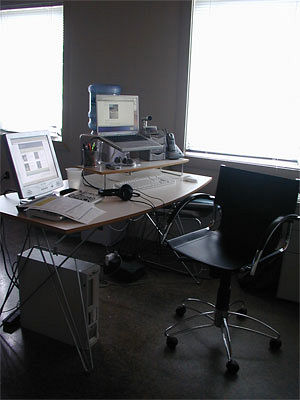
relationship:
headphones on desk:
[95, 181, 141, 203] [0, 154, 220, 380]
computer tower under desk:
[15, 245, 100, 355] [0, 154, 220, 380]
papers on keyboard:
[21, 193, 108, 228] [21, 187, 108, 226]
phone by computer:
[161, 128, 186, 161] [1, 148, 216, 398]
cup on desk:
[64, 165, 85, 191] [0, 154, 220, 380]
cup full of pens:
[76, 148, 101, 172] [81, 138, 96, 166]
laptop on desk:
[91, 89, 167, 153] [0, 154, 220, 380]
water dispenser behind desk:
[82, 79, 126, 172] [1, 146, 219, 398]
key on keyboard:
[132, 181, 140, 185] [104, 172, 177, 196]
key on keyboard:
[132, 177, 140, 185] [102, 173, 182, 198]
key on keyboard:
[143, 176, 150, 183] [104, 172, 177, 196]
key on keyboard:
[145, 178, 151, 187] [104, 172, 177, 196]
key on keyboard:
[141, 180, 147, 186] [104, 172, 177, 196]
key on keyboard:
[146, 182, 150, 185] [108, 171, 181, 193]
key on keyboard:
[151, 178, 157, 182] [105, 170, 178, 192]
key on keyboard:
[168, 175, 172, 182] [105, 170, 179, 197]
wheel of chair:
[224, 357, 240, 377] [154, 159, 290, 378]